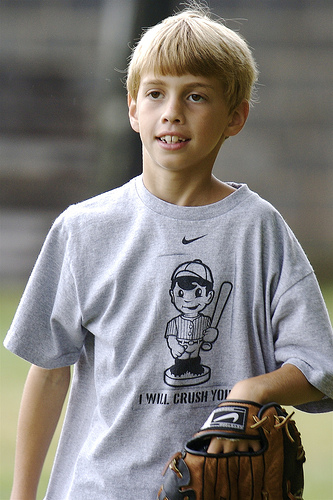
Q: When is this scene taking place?
A: Daytime.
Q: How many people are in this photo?
A: One.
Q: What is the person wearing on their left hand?
A: Catchers glove.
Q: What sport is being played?
A: Baseball.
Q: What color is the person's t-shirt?
A: Grey and black.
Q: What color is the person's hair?
A: Blonde.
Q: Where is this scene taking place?
A: On a baseball field.